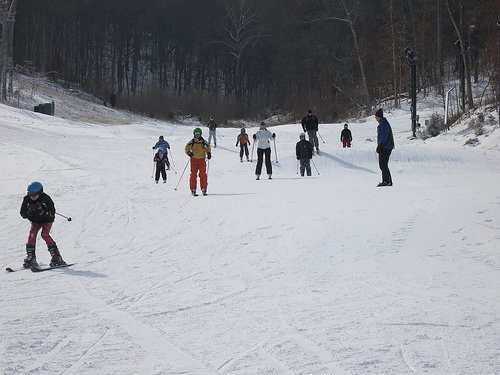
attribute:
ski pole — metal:
[172, 155, 196, 190]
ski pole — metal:
[315, 125, 325, 149]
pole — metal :
[208, 127, 278, 174]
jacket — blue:
[376, 117, 394, 151]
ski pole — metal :
[304, 154, 326, 182]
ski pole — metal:
[173, 168, 189, 188]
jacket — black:
[296, 138, 315, 163]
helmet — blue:
[25, 179, 44, 197]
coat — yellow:
[183, 134, 217, 164]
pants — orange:
[186, 152, 209, 193]